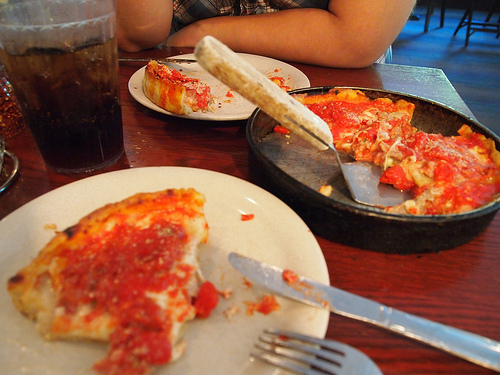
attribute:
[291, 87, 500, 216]
pizza — red, sliced, partially eaten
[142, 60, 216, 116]
pizza — partially eaten, a piece, peice, sliced, red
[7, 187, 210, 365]
pizza — red, peice, sliced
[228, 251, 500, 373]
knife — metal, silver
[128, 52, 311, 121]
plate — ceramic, white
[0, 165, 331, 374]
plate — white, ceramic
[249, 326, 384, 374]
fork — metallic, silver, metal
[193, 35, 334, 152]
handle — wooden, tan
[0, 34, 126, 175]
liquid — brown, brown-black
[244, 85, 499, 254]
pan — black, circular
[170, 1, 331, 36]
shirt — plaid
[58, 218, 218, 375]
sauce — red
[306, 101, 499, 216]
sauce — red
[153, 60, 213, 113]
sauce — red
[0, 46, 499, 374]
table — wood-patterned, brownish, wooden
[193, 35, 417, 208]
spatula — metal